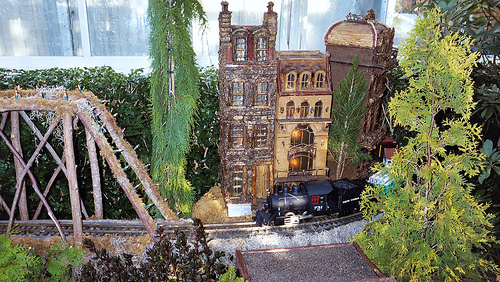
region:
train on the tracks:
[248, 179, 379, 231]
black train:
[250, 166, 377, 229]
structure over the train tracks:
[2, 86, 197, 254]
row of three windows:
[284, 72, 326, 89]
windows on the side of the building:
[283, 98, 328, 117]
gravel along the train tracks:
[210, 228, 367, 247]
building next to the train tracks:
[204, 7, 410, 229]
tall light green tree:
[354, 23, 499, 275]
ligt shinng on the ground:
[257, 228, 279, 247]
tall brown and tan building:
[222, 5, 392, 207]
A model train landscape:
[0, 1, 499, 280]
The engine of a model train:
[247, 172, 329, 234]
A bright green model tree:
[370, 4, 497, 279]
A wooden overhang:
[0, 80, 220, 251]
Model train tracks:
[0, 202, 366, 242]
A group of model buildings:
[214, 2, 403, 210]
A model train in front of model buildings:
[205, 0, 369, 227]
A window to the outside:
[1, 0, 386, 63]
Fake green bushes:
[0, 55, 222, 218]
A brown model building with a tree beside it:
[323, 3, 395, 173]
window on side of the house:
[286, 73, 296, 91]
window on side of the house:
[298, 68, 311, 92]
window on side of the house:
[312, 73, 328, 89]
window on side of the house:
[280, 100, 297, 123]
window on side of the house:
[299, 100, 309, 114]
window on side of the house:
[312, 97, 324, 114]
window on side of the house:
[232, 85, 249, 110]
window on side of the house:
[254, 84, 264, 104]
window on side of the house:
[235, 36, 249, 63]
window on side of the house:
[254, 34, 272, 61]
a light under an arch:
[290, 130, 306, 141]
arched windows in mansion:
[281, 65, 325, 91]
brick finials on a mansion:
[213, 4, 288, 29]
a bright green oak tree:
[363, 14, 488, 274]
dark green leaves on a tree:
[84, 237, 219, 279]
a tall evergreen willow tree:
[146, 5, 198, 197]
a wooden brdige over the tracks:
[10, 88, 157, 215]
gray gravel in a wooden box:
[246, 251, 358, 279]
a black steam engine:
[259, 180, 357, 225]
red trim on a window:
[306, 194, 325, 205]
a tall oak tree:
[377, 34, 491, 279]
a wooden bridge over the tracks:
[6, 85, 171, 230]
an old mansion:
[211, 11, 368, 190]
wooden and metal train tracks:
[94, 221, 154, 236]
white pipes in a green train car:
[369, 164, 387, 190]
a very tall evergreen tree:
[151, 4, 206, 201]